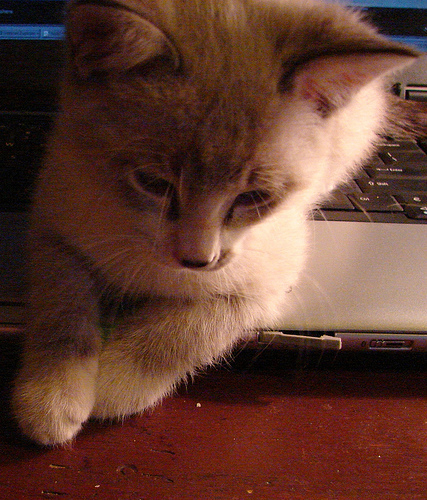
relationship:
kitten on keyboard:
[11, 0, 421, 437] [6, 111, 424, 220]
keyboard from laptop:
[6, 111, 424, 220] [0, 4, 424, 352]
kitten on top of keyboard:
[11, 0, 421, 437] [6, 111, 424, 220]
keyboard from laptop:
[6, 111, 424, 220] [317, 147, 416, 313]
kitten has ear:
[11, 0, 421, 437] [290, 40, 420, 127]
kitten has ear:
[11, 0, 421, 437] [62, 1, 187, 92]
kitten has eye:
[11, 0, 421, 437] [231, 184, 269, 213]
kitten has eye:
[11, 0, 421, 437] [134, 169, 176, 205]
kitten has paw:
[11, 0, 421, 437] [6, 349, 98, 448]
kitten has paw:
[11, 0, 421, 437] [88, 319, 175, 420]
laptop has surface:
[317, 147, 416, 313] [8, 222, 423, 351]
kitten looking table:
[11, 0, 421, 437] [0, 356, 424, 498]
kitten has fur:
[11, 0, 421, 437] [6, 0, 389, 451]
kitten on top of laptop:
[11, 0, 421, 437] [317, 147, 416, 313]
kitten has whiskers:
[11, 0, 421, 437] [253, 181, 333, 237]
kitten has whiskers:
[11, 0, 421, 437] [81, 131, 170, 212]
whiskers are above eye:
[253, 181, 333, 237] [231, 184, 269, 213]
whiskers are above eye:
[81, 131, 170, 212] [134, 169, 176, 205]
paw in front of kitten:
[6, 349, 98, 448] [11, 0, 421, 437]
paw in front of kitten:
[88, 319, 175, 420] [11, 0, 421, 437]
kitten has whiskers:
[11, 0, 421, 437] [32, 228, 159, 344]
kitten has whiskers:
[11, 0, 421, 437] [195, 248, 333, 344]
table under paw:
[0, 356, 424, 498] [6, 349, 98, 448]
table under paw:
[0, 356, 424, 498] [88, 319, 175, 420]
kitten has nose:
[11, 0, 421, 437] [175, 257, 212, 274]